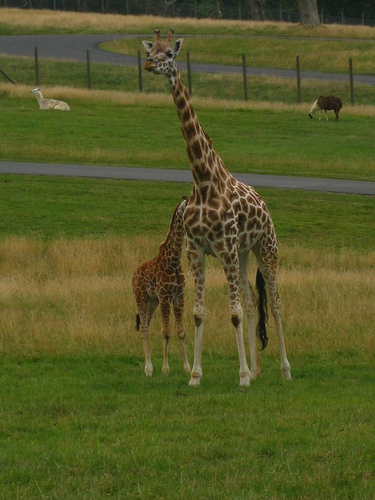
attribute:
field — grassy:
[1, 4, 373, 498]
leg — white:
[164, 319, 225, 394]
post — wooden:
[32, 45, 39, 87]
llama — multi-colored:
[292, 85, 347, 125]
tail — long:
[253, 262, 269, 350]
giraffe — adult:
[140, 25, 299, 387]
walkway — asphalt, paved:
[253, 169, 362, 201]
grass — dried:
[276, 226, 372, 352]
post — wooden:
[235, 50, 251, 101]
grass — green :
[263, 116, 352, 164]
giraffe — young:
[129, 189, 196, 377]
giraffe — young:
[130, 194, 192, 378]